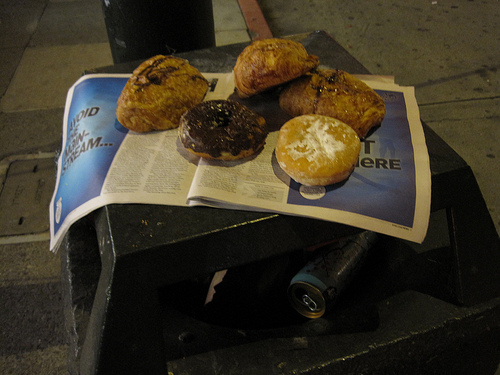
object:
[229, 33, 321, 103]
donut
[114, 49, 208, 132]
donut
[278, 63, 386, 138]
donut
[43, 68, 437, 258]
newspaper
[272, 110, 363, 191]
doughnut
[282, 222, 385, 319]
can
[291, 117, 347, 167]
powder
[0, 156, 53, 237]
sewer cover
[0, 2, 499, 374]
ground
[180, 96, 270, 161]
donuts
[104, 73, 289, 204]
area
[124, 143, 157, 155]
letters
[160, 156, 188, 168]
letters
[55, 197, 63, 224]
design label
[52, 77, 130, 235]
left side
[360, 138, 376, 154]
t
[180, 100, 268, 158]
chocolate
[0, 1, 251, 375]
sidewalk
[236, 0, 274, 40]
stripe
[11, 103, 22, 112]
spot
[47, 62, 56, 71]
spot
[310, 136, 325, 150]
center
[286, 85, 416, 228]
ad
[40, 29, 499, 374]
trash can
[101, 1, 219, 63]
pole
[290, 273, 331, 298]
ring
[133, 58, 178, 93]
drizzle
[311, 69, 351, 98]
drizzle